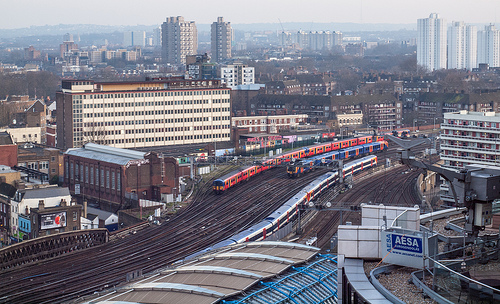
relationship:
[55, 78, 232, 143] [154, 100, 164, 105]
large building has windows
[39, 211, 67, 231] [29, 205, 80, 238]
adverstisment sign on building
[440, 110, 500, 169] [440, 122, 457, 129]
large building has balcony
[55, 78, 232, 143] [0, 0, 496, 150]
large building in city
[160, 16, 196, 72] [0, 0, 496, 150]
high rise building in city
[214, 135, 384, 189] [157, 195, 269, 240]
red train on railroad tracks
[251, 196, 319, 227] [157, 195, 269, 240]
silver train on railroad tracks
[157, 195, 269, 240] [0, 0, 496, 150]
railroad tracks in city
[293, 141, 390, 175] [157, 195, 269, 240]
train on railroad tracks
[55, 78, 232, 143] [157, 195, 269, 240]
large building next to railroad tracks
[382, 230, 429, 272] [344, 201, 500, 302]
aesa sign on building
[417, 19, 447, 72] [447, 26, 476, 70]
building next to or building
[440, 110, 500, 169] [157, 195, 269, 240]
large building by railroad tracks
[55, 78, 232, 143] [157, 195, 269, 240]
large building by railroad tracks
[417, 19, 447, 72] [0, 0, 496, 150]
building in city